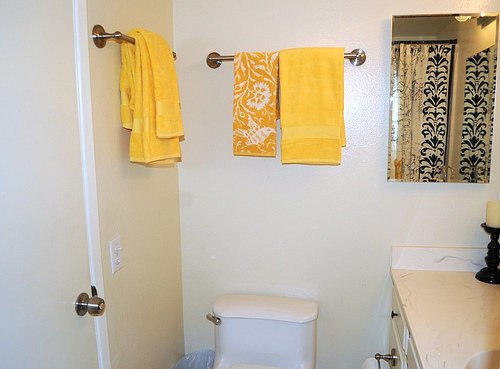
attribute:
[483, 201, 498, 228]
candle — black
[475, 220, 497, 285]
candle holder — black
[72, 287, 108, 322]
doorknob — silver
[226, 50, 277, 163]
towel — yellow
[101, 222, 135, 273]
light switch — on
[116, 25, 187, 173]
towel — yellow, hanging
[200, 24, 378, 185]
towels — yellow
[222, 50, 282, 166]
bath towel — floral pattern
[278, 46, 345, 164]
towel — yellow, gold, hanging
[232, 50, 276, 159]
towel — gold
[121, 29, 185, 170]
towel — gold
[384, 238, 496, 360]
counter — white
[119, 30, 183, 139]
handtowel — yellow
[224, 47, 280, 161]
towel — hanging, yellow, white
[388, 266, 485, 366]
counter — bathroom